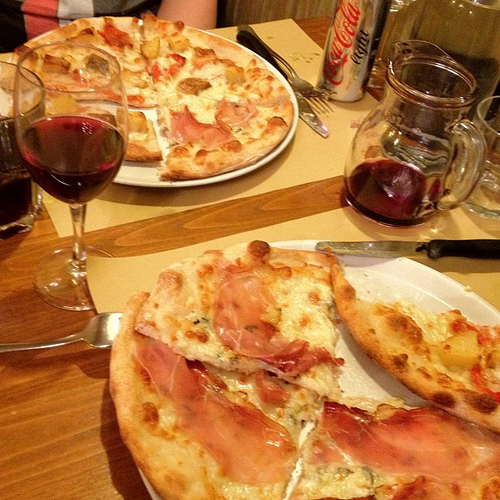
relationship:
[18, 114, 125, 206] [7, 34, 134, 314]
red wine in glass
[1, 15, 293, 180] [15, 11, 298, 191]
pizza on plate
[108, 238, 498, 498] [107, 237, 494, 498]
pizza on plate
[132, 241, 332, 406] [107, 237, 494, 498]
pie on plate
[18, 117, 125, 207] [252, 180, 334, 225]
red wine on table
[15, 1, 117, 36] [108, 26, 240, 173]
person sitting in front of pizza